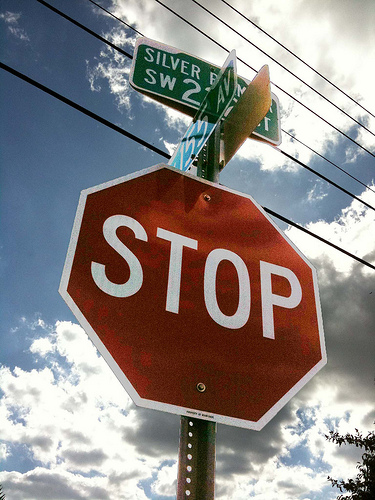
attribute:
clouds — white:
[84, 0, 373, 180]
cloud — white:
[0, 176, 375, 498]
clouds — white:
[169, 2, 370, 159]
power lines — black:
[48, 2, 373, 271]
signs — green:
[126, 33, 283, 174]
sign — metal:
[58, 185, 288, 390]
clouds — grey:
[87, 3, 374, 302]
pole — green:
[176, 107, 242, 499]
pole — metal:
[184, 106, 233, 177]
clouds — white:
[12, 267, 40, 309]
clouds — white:
[1, 0, 374, 499]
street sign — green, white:
[129, 35, 292, 140]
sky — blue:
[0, 1, 375, 498]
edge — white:
[65, 301, 137, 414]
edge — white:
[307, 275, 336, 359]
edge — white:
[95, 170, 133, 191]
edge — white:
[266, 222, 304, 261]